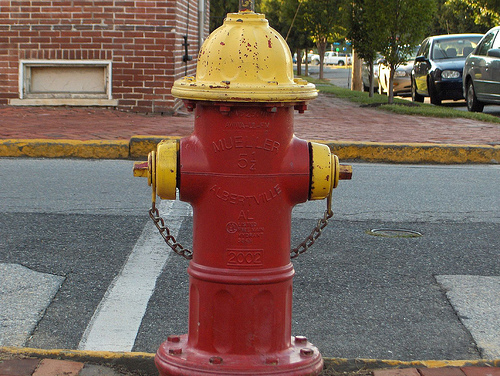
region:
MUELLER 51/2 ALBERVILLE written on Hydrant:
[200, 124, 287, 209]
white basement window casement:
[6, 57, 126, 111]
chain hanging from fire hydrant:
[138, 194, 345, 271]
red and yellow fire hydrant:
[130, 2, 350, 372]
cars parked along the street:
[350, 30, 499, 103]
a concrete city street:
[0, 157, 498, 353]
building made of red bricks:
[0, 3, 213, 118]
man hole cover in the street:
[367, 225, 429, 243]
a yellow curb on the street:
[4, 135, 496, 166]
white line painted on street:
[76, 146, 196, 368]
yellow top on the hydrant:
[173, 13, 318, 100]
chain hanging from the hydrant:
[288, 200, 332, 260]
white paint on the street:
[81, 201, 183, 353]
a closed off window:
[18, 58, 112, 98]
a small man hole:
[372, 225, 420, 237]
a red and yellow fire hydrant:
[140, 8, 350, 372]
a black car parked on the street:
[414, 33, 478, 103]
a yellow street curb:
[0, 135, 498, 163]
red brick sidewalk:
[0, 88, 493, 142]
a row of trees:
[278, 2, 398, 91]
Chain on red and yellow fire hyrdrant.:
[309, 232, 324, 248]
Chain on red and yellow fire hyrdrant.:
[450, 266, 457, 328]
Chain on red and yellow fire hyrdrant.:
[103, 256, 209, 292]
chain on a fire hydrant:
[140, 192, 192, 266]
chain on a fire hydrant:
[290, 191, 339, 268]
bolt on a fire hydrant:
[335, 160, 356, 184]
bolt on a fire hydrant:
[132, 151, 146, 182]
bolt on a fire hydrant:
[290, 99, 312, 117]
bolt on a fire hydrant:
[298, 345, 317, 360]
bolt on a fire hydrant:
[262, 350, 279, 367]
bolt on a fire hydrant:
[205, 354, 225, 366]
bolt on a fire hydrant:
[165, 342, 181, 357]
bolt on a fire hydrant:
[165, 328, 181, 345]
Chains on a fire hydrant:
[144, 199, 336, 266]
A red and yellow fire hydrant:
[129, 7, 358, 374]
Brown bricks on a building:
[1, 2, 211, 115]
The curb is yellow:
[1, 133, 498, 170]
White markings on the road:
[2, 189, 498, 361]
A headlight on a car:
[436, 65, 463, 85]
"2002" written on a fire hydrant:
[221, 249, 268, 271]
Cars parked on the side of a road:
[356, 23, 498, 120]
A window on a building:
[15, 53, 115, 99]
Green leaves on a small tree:
[362, 0, 441, 106]